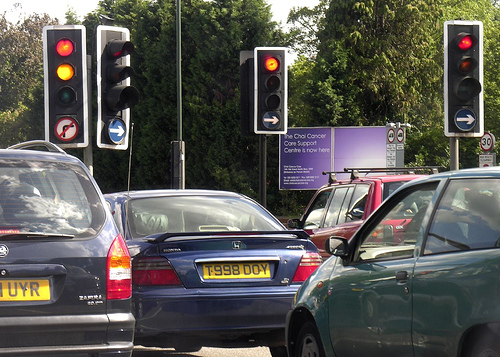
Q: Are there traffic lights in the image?
A: Yes, there is a traffic light.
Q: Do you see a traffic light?
A: Yes, there is a traffic light.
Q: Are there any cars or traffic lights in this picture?
A: Yes, there is a traffic light.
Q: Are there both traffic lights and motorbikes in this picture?
A: No, there is a traffic light but no motorcycles.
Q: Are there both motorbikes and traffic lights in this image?
A: No, there is a traffic light but no motorcycles.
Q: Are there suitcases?
A: No, there are no suitcases.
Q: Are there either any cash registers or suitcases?
A: No, there are no suitcases or cash registers.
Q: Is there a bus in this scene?
A: No, there are no buses.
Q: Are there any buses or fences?
A: No, there are no buses or fences.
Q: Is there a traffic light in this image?
A: Yes, there is a traffic light.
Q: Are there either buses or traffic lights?
A: Yes, there is a traffic light.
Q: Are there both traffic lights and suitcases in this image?
A: No, there is a traffic light but no suitcases.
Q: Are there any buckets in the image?
A: No, there are no buckets.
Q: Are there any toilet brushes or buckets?
A: No, there are no buckets or toilet brushes.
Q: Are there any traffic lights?
A: Yes, there is a traffic light.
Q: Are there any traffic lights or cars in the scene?
A: Yes, there is a traffic light.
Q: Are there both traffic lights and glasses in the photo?
A: No, there is a traffic light but no glasses.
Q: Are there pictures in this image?
A: No, there are no pictures.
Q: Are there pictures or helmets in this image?
A: No, there are no pictures or helmets.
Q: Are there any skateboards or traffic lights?
A: Yes, there is a traffic light.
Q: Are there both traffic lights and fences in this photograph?
A: No, there is a traffic light but no fences.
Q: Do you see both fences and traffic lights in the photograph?
A: No, there is a traffic light but no fences.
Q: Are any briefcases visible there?
A: No, there are no briefcases.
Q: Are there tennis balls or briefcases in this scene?
A: No, there are no briefcases or tennis balls.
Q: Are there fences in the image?
A: No, there are no fences.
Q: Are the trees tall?
A: Yes, the trees are tall.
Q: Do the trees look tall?
A: Yes, the trees are tall.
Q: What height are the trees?
A: The trees are tall.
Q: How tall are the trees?
A: The trees are tall.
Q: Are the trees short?
A: No, the trees are tall.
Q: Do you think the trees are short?
A: No, the trees are tall.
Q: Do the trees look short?
A: No, the trees are tall.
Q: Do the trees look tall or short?
A: The trees are tall.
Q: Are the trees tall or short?
A: The trees are tall.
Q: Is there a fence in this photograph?
A: No, there are no fences.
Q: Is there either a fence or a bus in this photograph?
A: No, there are no fences or buses.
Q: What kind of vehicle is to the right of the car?
A: The vehicle is a van.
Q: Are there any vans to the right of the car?
A: Yes, there is a van to the right of the car.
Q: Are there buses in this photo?
A: No, there are no buses.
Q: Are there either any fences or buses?
A: No, there are no buses or fences.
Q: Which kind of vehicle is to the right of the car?
A: The vehicle is a van.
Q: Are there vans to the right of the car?
A: Yes, there is a van to the right of the car.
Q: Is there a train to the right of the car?
A: No, there is a van to the right of the car.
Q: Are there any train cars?
A: No, there are no train cars.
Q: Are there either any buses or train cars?
A: No, there are no train cars or buses.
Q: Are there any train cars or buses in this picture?
A: No, there are no train cars or buses.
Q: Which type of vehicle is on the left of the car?
A: The vehicle is a van.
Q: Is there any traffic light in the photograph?
A: Yes, there is a traffic light.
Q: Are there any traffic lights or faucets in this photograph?
A: Yes, there is a traffic light.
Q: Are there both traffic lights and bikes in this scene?
A: No, there is a traffic light but no bikes.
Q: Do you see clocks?
A: No, there are no clocks.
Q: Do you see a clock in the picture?
A: No, there are no clocks.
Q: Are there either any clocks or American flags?
A: No, there are no clocks or American flags.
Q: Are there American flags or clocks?
A: No, there are no clocks or American flags.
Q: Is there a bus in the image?
A: No, there are no buses.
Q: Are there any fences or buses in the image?
A: No, there are no buses or fences.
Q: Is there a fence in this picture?
A: No, there are no fences.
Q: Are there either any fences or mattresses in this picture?
A: No, there are no fences or mattresses.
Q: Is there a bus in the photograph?
A: No, there are no buses.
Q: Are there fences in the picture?
A: No, there are no fences.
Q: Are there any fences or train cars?
A: No, there are no fences or train cars.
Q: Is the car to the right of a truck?
A: No, the car is to the right of a van.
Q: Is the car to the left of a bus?
A: No, the car is to the left of the van.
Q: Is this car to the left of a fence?
A: No, the car is to the left of the van.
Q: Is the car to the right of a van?
A: No, the car is to the left of a van.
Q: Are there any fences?
A: No, there are no fences.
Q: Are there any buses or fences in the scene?
A: No, there are no fences or buses.